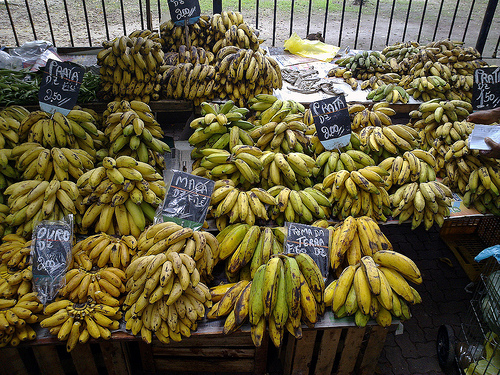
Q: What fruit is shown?
A: Bananas.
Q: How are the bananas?
A: Yellow.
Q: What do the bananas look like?
A: Bunch.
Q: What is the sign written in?
A: Chalk.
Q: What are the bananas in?
A: Bunches.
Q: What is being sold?
A: Bananas.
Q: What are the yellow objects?
A: Bananas.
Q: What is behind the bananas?
A: Fence.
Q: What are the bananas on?
A: Table.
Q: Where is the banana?
A: On the table?.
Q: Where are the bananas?
A: On the table?.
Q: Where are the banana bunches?
A: On the table.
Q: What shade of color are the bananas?
A: Yellow.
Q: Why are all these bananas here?
A: For sale.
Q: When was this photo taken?
A: During the day.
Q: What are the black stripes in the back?
A: Iron fencing.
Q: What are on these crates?
A: Bananas.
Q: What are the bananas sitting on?
A: Crates.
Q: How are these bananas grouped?
A: In bunches.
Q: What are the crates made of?
A: Wood.